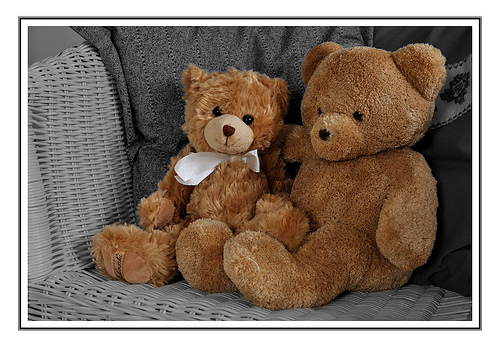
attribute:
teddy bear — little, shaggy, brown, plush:
[91, 65, 294, 293]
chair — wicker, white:
[28, 27, 471, 321]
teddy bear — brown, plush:
[177, 42, 448, 309]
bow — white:
[173, 149, 259, 186]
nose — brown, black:
[223, 125, 234, 135]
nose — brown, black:
[320, 129, 329, 139]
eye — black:
[212, 107, 222, 117]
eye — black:
[243, 115, 253, 123]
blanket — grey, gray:
[70, 25, 372, 228]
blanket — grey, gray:
[373, 26, 471, 297]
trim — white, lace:
[426, 53, 470, 130]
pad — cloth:
[101, 247, 149, 284]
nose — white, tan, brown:
[204, 115, 254, 154]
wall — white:
[29, 26, 97, 65]